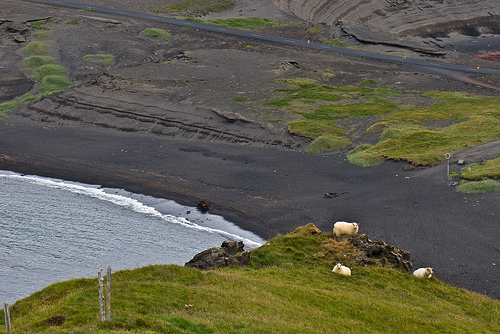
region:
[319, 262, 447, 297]
sheep on the grass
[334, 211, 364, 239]
the sheep on the rocks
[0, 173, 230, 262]
the water is calm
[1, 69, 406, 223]
the sand is black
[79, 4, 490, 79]
the road is empty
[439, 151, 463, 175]
the sign in the sand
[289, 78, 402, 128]
patches of grass in the sand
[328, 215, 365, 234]
the sheep is white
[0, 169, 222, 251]
small waves on the water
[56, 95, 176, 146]
striations in the sand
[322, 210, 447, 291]
three white sheep grazing on the mountain.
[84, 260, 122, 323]
Two old tree trunks standing side by side.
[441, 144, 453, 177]
Stop sign in the middle of nowhere.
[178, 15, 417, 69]
Roadway with white lines painted on it.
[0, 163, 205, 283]
Body of water that has small waves breaking on the shore.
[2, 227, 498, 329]
Mountainside that is covered in grass and sharp rocks.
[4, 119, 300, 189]
Shore covered in black sand.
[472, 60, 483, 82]
Sign on the roadway that is orange in color.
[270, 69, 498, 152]
Small patches of grass growing on the ground.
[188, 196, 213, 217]
Large item on the coastline.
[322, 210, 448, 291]
three sheep on a hillside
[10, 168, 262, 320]
the edge of a body of water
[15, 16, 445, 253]
a dark sandy beach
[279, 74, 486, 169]
a patch of grass in the middle of the sand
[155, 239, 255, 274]
a rocky outcrop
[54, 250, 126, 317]
two fenceposts sticking out of the ground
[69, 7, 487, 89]
a deserted road in the distance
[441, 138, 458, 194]
a red sign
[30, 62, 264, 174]
marks left by erosion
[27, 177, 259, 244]
foam from a breaking wave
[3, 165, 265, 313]
seashore with a little waves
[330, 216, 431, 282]
three sheeps on a mountain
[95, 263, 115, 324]
wooden poles in the ground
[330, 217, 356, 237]
sheep standing on a rock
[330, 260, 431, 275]
two sheeps lying in the ground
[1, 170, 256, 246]
white foam in the sea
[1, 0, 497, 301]
large sandy seashore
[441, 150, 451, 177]
red and white signboard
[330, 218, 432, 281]
three white wolly sheeps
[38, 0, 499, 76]
thin highway in the beach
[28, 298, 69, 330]
part of the green landscape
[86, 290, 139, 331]
part of the green landscape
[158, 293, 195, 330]
part of the green landscape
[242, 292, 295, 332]
part of the green landscape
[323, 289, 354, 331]
part of the green landscape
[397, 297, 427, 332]
part of the green landscape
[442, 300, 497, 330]
part of the green landscape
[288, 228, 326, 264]
part of the green landscape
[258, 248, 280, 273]
part of the green landscape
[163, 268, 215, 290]
part of the green landscape